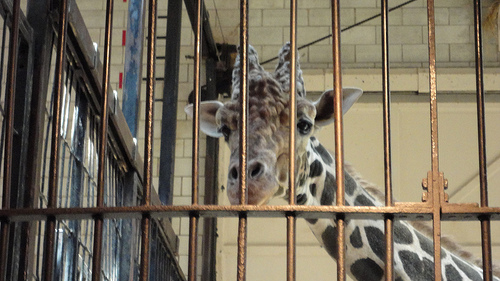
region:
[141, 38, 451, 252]
A giraffe behind a cage.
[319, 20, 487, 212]
Bar of the cage is rusty.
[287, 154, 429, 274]
The giraffe has brown spots.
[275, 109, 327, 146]
The eye of the giraffe.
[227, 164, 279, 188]
The nose of the giraffe.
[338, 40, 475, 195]
The wall is yellow.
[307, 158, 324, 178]
black spot on giraffe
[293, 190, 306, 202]
black spot on giraffe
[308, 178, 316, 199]
black spot on giraffe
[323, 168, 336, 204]
black spot on giraffe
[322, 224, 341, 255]
black spot on giraffe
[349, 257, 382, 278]
black spot on giraffe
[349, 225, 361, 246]
black spot on giraffe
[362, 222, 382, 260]
black spot on giraffe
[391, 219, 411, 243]
black spot on giraffe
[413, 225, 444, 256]
black spot on giraffe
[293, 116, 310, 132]
Eye on a giraffe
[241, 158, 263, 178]
Nostril on a giraffe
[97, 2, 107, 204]
Copper pipe on a cage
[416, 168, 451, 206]
Hinges on a fence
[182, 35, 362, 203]
Giraffe's head peering through cage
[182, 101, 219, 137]
Ear on a giraffe's head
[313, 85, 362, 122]
Ear on a giraffe's head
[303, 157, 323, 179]
Black spot on a giraffe's neck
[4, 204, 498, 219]
Horizontal bar across a cage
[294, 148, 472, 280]
A long neck on a giraffe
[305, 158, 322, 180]
spot on the giraffe in the cage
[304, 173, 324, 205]
spot on the giraffe in the cage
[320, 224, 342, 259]
spot on the giraffe in the cage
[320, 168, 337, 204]
spot on the giraffe in the cage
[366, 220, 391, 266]
spot on the giraffe in the cage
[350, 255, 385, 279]
spot on the giraffe in the cage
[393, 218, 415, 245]
spot on the giraffe in the cage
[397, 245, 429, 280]
spot on the giraffe in the cage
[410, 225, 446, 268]
spot on the giraffe in the cage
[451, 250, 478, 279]
spot on the giraffe in the cage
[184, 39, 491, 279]
Adult giraffe in enclosure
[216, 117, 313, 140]
Black eyes on giraffe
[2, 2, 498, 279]
Metal bars of enclosure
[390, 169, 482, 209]
Metal bracket connecting enclosure section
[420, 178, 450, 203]
Metal bolts attaching brackets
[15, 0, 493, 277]
Cinderblock wall in background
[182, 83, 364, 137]
Ears on giraffe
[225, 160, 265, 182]
Nostrils on giraffe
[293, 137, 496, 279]
Long neck on giraffe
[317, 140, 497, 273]
brown hairs on giraffe mane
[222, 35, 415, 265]
A giraffe behind the cage.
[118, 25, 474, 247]
The bars on the cage is rusty.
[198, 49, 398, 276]
The giraffe is brown and white.